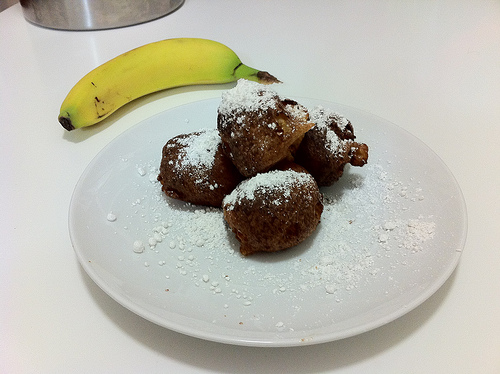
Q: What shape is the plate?
A: Round.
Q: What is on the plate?
A: Food.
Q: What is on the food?
A: Powdered sugar.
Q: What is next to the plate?
A: A banana.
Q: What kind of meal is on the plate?
A: Dessert.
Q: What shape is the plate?
A: Round.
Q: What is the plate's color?
A: White.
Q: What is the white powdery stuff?
A: Powdered sugar.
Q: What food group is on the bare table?
A: Fruit.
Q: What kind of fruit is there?
A: A banana.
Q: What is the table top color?
A: White.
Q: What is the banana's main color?
A: Yellow.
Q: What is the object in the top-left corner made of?
A: Metal.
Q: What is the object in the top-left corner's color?
A: Silver.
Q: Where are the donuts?
A: On the white plate.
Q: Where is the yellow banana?
A: Behind the plate.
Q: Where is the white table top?
A: Under the plate.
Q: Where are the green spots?
A: On the banana.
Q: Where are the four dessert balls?
A: On the white plate.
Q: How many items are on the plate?
A: Four.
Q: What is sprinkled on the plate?
A: Powdered sugar.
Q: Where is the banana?
A: Next to the plate.